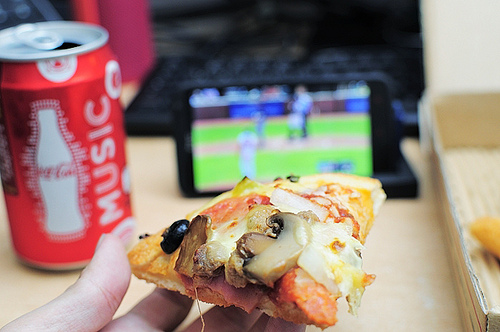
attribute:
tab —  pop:
[16, 19, 66, 54]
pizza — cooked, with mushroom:
[138, 187, 415, 329]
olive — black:
[161, 217, 191, 237]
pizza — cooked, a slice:
[123, 153, 393, 330]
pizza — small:
[123, 170, 415, 324]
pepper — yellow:
[225, 172, 269, 192]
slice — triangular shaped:
[124, 171, 389, 326]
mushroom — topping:
[237, 213, 314, 286]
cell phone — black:
[175, 72, 399, 198]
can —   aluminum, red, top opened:
[1, 13, 136, 269]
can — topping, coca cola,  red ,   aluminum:
[2, 18, 143, 281]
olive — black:
[158, 217, 193, 254]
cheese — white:
[313, 180, 373, 232]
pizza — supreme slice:
[152, 169, 347, 304]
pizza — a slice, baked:
[126, 173, 373, 328]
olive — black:
[162, 221, 191, 249]